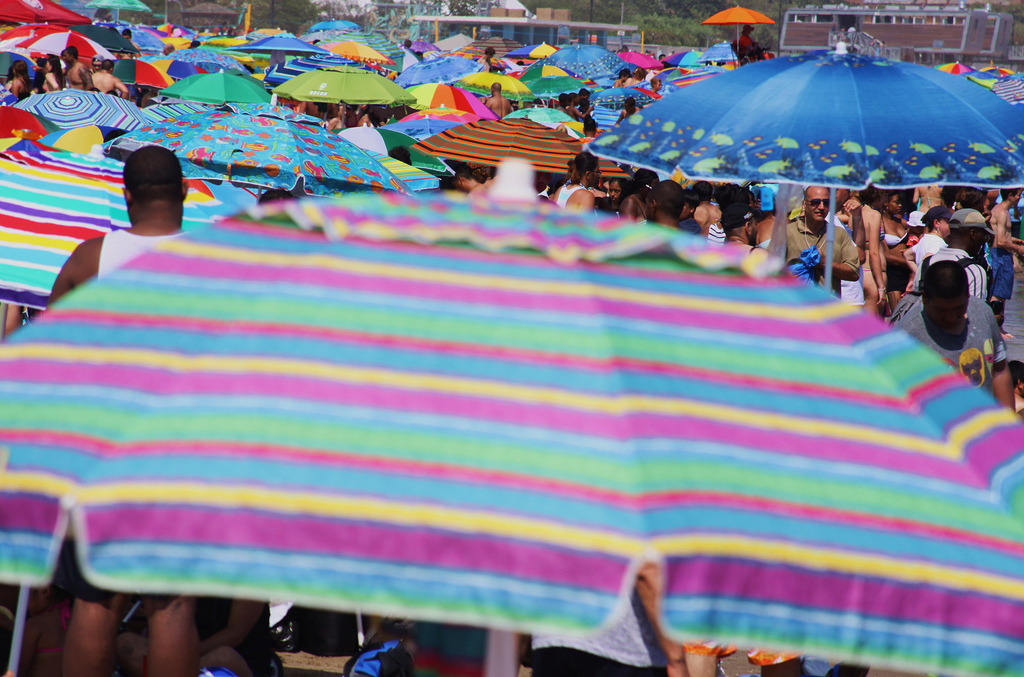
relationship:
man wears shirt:
[32, 133, 195, 308] [84, 218, 188, 281]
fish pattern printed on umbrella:
[119, 98, 407, 192] [96, 91, 418, 197]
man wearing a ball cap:
[922, 208, 996, 299] [948, 209, 995, 236]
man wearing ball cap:
[949, 190, 1006, 337] [948, 209, 995, 236]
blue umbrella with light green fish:
[604, 28, 1017, 219] [843, 124, 883, 166]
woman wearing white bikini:
[867, 178, 917, 323] [878, 212, 920, 264]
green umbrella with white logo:
[269, 50, 436, 133] [303, 80, 338, 107]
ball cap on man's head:
[938, 206, 1006, 228] [923, 186, 1001, 251]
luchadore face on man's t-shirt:
[956, 342, 1004, 386] [887, 270, 1004, 359]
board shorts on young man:
[979, 236, 1021, 289] [977, 173, 1021, 331]